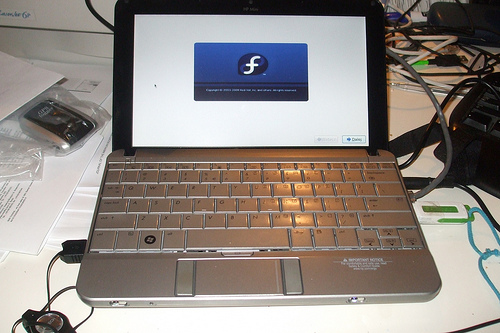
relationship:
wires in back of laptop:
[390, 13, 488, 83] [72, 1, 442, 302]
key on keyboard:
[171, 197, 190, 211] [76, 149, 441, 308]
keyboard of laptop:
[76, 149, 441, 308] [72, 1, 442, 302]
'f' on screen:
[237, 51, 269, 78] [132, 6, 367, 143]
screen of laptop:
[132, 6, 367, 143] [72, 1, 442, 302]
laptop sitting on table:
[72, 1, 442, 302] [381, 22, 496, 307]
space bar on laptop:
[178, 225, 296, 250] [93, 5, 456, 272]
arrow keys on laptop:
[364, 229, 424, 247] [72, 1, 442, 302]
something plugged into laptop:
[9, 238, 94, 331] [72, 1, 442, 302]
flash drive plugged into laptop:
[407, 196, 477, 229] [74, 1, 443, 309]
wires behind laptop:
[382, 2, 492, 114] [72, 1, 442, 302]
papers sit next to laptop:
[0, 50, 120, 260] [74, 1, 443, 309]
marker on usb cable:
[411, 54, 429, 70] [435, 52, 466, 68]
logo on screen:
[236, 50, 268, 77] [129, 13, 371, 151]